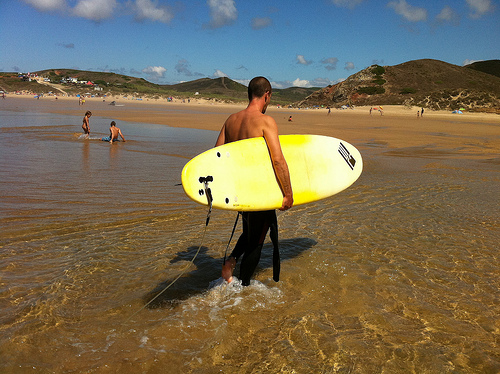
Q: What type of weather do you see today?
A: It is clear.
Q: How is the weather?
A: It is clear.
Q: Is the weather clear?
A: Yes, it is clear.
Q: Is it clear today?
A: Yes, it is clear.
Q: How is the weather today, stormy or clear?
A: It is clear.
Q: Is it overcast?
A: No, it is clear.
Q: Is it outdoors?
A: Yes, it is outdoors.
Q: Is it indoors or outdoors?
A: It is outdoors.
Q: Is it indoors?
A: No, it is outdoors.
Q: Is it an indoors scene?
A: No, it is outdoors.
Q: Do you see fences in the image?
A: No, there are no fences.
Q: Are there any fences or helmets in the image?
A: No, there are no fences or helmets.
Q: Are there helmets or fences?
A: No, there are no fences or helmets.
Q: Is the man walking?
A: Yes, the man is walking.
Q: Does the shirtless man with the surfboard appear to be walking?
A: Yes, the man is walking.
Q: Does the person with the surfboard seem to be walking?
A: Yes, the man is walking.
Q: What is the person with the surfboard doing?
A: The man is walking.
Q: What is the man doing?
A: The man is walking.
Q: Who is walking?
A: The man is walking.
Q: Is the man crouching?
A: No, the man is walking.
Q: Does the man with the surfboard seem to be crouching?
A: No, the man is walking.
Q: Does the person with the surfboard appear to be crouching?
A: No, the man is walking.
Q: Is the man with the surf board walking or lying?
A: The man is walking.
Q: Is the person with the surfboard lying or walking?
A: The man is walking.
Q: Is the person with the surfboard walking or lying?
A: The man is walking.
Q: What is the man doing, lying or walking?
A: The man is walking.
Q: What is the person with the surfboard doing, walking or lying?
A: The man is walking.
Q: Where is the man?
A: The man is in the water.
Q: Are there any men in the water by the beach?
A: Yes, there is a man in the water.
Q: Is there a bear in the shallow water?
A: No, there is a man in the water.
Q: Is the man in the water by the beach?
A: Yes, the man is in the water.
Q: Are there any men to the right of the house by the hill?
A: Yes, there is a man to the right of the house.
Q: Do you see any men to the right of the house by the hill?
A: Yes, there is a man to the right of the house.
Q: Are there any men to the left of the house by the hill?
A: No, the man is to the right of the house.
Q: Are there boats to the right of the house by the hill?
A: No, there is a man to the right of the house.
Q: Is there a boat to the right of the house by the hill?
A: No, there is a man to the right of the house.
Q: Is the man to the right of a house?
A: Yes, the man is to the right of a house.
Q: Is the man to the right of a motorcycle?
A: No, the man is to the right of a house.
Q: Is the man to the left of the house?
A: No, the man is to the right of the house.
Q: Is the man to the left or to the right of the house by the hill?
A: The man is to the right of the house.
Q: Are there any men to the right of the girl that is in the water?
A: Yes, there is a man to the right of the girl.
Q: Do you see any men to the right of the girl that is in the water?
A: Yes, there is a man to the right of the girl.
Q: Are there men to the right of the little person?
A: Yes, there is a man to the right of the girl.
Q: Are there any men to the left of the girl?
A: No, the man is to the right of the girl.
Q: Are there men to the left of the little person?
A: No, the man is to the right of the girl.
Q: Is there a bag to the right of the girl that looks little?
A: No, there is a man to the right of the girl.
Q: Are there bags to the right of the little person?
A: No, there is a man to the right of the girl.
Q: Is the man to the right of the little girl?
A: Yes, the man is to the right of the girl.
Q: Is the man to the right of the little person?
A: Yes, the man is to the right of the girl.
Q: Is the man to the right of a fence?
A: No, the man is to the right of the girl.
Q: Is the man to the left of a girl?
A: No, the man is to the right of a girl.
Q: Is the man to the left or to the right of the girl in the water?
A: The man is to the right of the girl.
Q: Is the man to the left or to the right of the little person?
A: The man is to the right of the girl.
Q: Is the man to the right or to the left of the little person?
A: The man is to the right of the girl.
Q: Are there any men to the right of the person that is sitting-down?
A: Yes, there is a man to the right of the person.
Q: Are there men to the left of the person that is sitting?
A: No, the man is to the right of the person.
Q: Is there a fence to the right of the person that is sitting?
A: No, there is a man to the right of the person.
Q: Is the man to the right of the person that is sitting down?
A: Yes, the man is to the right of the person.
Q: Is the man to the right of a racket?
A: No, the man is to the right of the person.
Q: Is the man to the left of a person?
A: No, the man is to the right of a person.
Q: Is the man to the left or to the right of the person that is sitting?
A: The man is to the right of the person.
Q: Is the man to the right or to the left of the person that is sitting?
A: The man is to the right of the person.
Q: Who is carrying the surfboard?
A: The man is carrying the surfboard.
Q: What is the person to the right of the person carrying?
A: The man is carrying a surf board.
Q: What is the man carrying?
A: The man is carrying a surf board.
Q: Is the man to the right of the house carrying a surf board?
A: Yes, the man is carrying a surf board.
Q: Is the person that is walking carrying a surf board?
A: Yes, the man is carrying a surf board.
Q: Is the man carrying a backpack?
A: No, the man is carrying a surf board.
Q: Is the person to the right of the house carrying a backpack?
A: No, the man is carrying a surf board.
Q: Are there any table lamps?
A: No, there are no table lamps.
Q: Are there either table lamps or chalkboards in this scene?
A: No, there are no table lamps or chalkboards.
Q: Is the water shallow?
A: Yes, the water is shallow.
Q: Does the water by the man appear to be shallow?
A: Yes, the water is shallow.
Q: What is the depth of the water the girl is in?
A: The water is shallow.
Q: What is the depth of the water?
A: The water is shallow.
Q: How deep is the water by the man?
A: The water is shallow.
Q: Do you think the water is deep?
A: No, the water is shallow.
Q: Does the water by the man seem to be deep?
A: No, the water is shallow.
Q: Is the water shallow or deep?
A: The water is shallow.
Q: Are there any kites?
A: No, there are no kites.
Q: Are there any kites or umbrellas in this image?
A: No, there are no kites or umbrellas.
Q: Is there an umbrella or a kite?
A: No, there are no kites or umbrellas.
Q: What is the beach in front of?
A: The beach is in front of the hill.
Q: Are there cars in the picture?
A: No, there are no cars.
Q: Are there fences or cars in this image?
A: No, there are no cars or fences.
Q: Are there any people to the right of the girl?
A: Yes, there is a person to the right of the girl.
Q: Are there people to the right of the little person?
A: Yes, there is a person to the right of the girl.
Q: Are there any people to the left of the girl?
A: No, the person is to the right of the girl.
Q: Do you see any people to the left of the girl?
A: No, the person is to the right of the girl.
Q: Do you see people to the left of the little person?
A: No, the person is to the right of the girl.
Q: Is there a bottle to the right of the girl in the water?
A: No, there is a person to the right of the girl.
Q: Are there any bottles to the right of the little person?
A: No, there is a person to the right of the girl.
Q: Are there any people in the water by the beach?
A: Yes, there is a person in the water.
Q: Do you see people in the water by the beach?
A: Yes, there is a person in the water.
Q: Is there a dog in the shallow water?
A: No, there is a person in the water.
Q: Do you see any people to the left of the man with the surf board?
A: Yes, there is a person to the left of the man.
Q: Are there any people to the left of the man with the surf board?
A: Yes, there is a person to the left of the man.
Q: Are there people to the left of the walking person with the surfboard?
A: Yes, there is a person to the left of the man.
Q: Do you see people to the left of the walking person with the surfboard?
A: Yes, there is a person to the left of the man.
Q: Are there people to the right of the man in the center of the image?
A: No, the person is to the left of the man.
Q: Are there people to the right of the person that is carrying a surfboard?
A: No, the person is to the left of the man.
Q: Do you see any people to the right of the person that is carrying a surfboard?
A: No, the person is to the left of the man.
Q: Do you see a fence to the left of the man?
A: No, there is a person to the left of the man.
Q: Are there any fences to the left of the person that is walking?
A: No, there is a person to the left of the man.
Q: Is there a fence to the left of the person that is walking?
A: No, there is a person to the left of the man.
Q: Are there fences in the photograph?
A: No, there are no fences.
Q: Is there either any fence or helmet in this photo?
A: No, there are no fences or helmets.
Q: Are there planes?
A: No, there are no planes.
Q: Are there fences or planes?
A: No, there are no planes or fences.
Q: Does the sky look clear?
A: Yes, the sky is clear.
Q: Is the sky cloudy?
A: No, the sky is clear.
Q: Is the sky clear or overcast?
A: The sky is clear.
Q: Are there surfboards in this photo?
A: Yes, there is a surfboard.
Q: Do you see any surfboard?
A: Yes, there is a surfboard.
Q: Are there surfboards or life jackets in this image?
A: Yes, there is a surfboard.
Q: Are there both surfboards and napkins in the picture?
A: No, there is a surfboard but no napkins.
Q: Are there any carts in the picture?
A: No, there are no carts.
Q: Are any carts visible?
A: No, there are no carts.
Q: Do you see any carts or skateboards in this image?
A: No, there are no carts or skateboards.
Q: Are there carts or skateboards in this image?
A: No, there are no carts or skateboards.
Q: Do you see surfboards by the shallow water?
A: Yes, there is a surfboard by the water.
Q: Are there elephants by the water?
A: No, there is a surfboard by the water.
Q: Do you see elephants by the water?
A: No, there is a surfboard by the water.